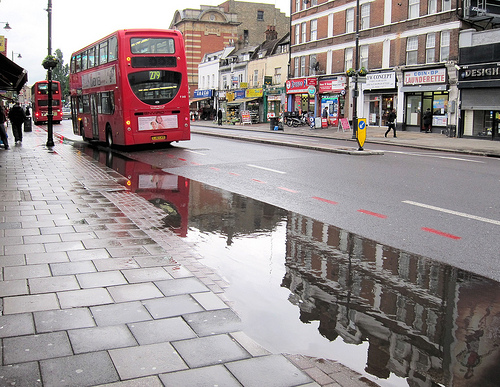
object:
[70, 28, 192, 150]
bus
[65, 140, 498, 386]
water puddle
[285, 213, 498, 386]
building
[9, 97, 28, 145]
person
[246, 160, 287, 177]
line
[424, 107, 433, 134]
person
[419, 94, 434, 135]
door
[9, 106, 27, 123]
back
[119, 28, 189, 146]
back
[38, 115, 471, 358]
right lane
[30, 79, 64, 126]
bus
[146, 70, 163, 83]
279 number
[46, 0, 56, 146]
lamp post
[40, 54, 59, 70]
plant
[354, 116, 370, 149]
flag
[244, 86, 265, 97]
sign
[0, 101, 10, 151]
person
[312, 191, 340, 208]
line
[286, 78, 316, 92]
sign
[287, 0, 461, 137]
building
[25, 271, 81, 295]
sidewalk brick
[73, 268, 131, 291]
another brick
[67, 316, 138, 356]
sidewalk brick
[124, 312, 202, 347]
another brick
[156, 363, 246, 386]
sidewalk brick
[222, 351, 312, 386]
another brick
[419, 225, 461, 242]
dash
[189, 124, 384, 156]
walkway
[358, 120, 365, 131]
circle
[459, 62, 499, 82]
design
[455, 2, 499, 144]
building front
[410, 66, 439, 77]
words coin op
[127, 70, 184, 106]
window